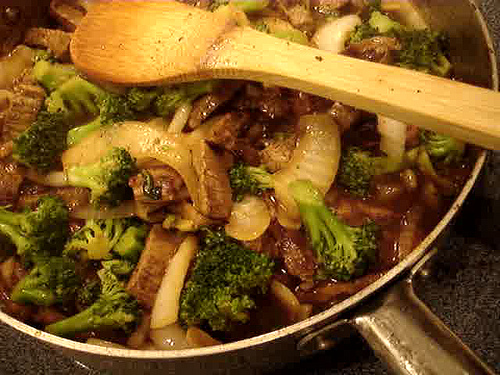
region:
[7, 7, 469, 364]
a silver pot with vegetables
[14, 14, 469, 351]
a pot with vegetables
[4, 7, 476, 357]
a pot of mixed vegetables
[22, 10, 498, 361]
a silver pot of mixed vegetables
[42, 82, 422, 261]
cooked broccoli and onions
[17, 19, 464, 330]
sauteed vegetables in a pot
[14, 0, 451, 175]
wooden spoon used to stir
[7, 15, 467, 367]
cooked onions and broccoli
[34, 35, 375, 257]
cut broccoli and sliced onions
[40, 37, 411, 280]
mixed vegetables cooked in a juice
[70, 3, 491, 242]
the spoon is made of wood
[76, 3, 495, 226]
the spoon is brown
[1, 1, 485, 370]
the food is in a pan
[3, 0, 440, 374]
broccoli meat and onions are in pan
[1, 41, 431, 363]
the broccoli is green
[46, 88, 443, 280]
the meat is brown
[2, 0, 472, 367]
the pan is made of metal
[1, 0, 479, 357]
the pan is silver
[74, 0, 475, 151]
the spoon has speckles of food on it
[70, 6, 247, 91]
the spoon is wet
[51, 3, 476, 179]
wooden spoon in stir fry dish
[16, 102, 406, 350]
onions, broccoli, and beef in dish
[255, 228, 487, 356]
pan handle for holding dish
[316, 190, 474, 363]
pan resting on countertop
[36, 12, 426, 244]
wooden spoon stirring beef and vegetable stew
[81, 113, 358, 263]
large onions in stir fry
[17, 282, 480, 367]
large steel pan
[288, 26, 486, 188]
wooden spoon handle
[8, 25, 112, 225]
broccoli and beef in stew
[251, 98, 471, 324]
simmering stew in pan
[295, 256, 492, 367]
handle of metal skillet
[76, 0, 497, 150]
wooden spoon on top of skillet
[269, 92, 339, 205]
sliced cooked onion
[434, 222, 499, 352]
gray speckled counter top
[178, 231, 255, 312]
top of green broccoli floret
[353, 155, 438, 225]
brown gravy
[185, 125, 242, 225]
sliced cooked beef strips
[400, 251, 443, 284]
metal screw holding handle to skillet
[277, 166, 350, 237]
green broccoli stem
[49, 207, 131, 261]
cut stem of green broccoli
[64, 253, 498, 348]
silver metal pot with food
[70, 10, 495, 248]
light wooden spoon stirring food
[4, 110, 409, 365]
green broccoli in food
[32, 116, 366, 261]
cooked onions in food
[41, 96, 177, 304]
broccoli is chopped up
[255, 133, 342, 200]
onion is white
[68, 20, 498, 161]
wooden spoon used in cooking process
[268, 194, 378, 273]
dark and light green broccoli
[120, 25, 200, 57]
food bits on spoon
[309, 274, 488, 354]
silver handle of pot